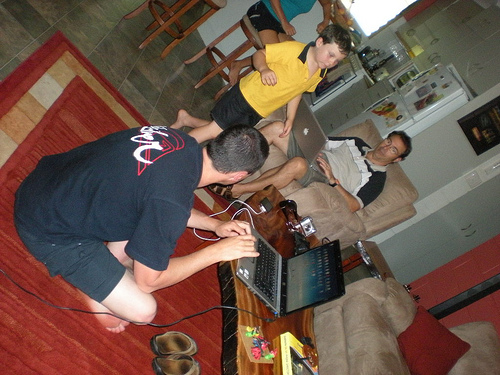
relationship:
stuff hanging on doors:
[368, 61, 458, 140] [343, 61, 468, 141]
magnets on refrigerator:
[400, 61, 450, 114] [323, 63, 470, 139]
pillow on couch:
[395, 304, 472, 374] [304, 271, 499, 368]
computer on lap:
[291, 100, 331, 177] [274, 120, 331, 182]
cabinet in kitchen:
[419, 29, 491, 77] [128, 1, 498, 171]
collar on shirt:
[301, 42, 329, 79] [237, 42, 324, 116]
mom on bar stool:
[224, 0, 333, 86] [181, 14, 266, 89]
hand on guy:
[218, 235, 260, 262] [12, 123, 270, 336]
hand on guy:
[214, 219, 251, 238] [12, 123, 270, 336]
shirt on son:
[234, 40, 327, 114] [167, 24, 354, 144]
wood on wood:
[150, 12, 168, 33] [123, 0, 229, 60]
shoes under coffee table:
[148, 325, 200, 373] [220, 167, 327, 372]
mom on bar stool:
[243, 0, 336, 40] [186, 14, 261, 92]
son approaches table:
[233, 39, 366, 94] [201, 261, 273, 355]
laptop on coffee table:
[230, 210, 347, 321] [216, 183, 324, 373]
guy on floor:
[7, 120, 273, 336] [2, 0, 226, 372]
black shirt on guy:
[14, 119, 204, 276] [7, 120, 273, 336]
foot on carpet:
[83, 295, 131, 336] [0, 31, 241, 374]